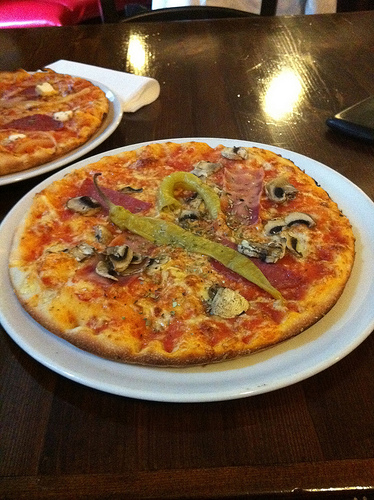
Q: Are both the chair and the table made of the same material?
A: Yes, both the chair and the table are made of wood.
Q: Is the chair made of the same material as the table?
A: Yes, both the chair and the table are made of wood.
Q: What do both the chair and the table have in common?
A: The material, both the chair and the table are wooden.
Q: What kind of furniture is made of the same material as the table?
A: The chair is made of the same material as the table.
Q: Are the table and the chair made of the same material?
A: Yes, both the table and the chair are made of wood.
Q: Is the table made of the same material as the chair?
A: Yes, both the table and the chair are made of wood.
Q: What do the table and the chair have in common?
A: The material, both the table and the chair are wooden.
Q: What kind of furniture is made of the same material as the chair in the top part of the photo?
A: The table is made of the same material as the chair.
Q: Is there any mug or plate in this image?
A: Yes, there is a plate.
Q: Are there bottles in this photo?
A: No, there are no bottles.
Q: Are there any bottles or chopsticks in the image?
A: No, there are no bottles or chopsticks.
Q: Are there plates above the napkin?
A: Yes, there is a plate above the napkin.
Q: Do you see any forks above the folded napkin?
A: No, there is a plate above the napkin.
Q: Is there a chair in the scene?
A: Yes, there is a chair.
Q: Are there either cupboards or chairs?
A: Yes, there is a chair.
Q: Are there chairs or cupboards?
A: Yes, there is a chair.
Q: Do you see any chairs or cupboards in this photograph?
A: Yes, there is a chair.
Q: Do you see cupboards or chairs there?
A: Yes, there is a chair.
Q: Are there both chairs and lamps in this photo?
A: No, there is a chair but no lamps.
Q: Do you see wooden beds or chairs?
A: Yes, there is a wood chair.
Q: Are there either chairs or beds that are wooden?
A: Yes, the chair is wooden.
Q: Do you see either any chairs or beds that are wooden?
A: Yes, the chair is wooden.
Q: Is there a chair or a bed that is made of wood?
A: Yes, the chair is made of wood.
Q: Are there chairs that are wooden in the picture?
A: Yes, there is a wood chair.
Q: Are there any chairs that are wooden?
A: Yes, there is a chair that is wooden.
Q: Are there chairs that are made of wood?
A: Yes, there is a chair that is made of wood.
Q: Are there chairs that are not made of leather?
A: Yes, there is a chair that is made of wood.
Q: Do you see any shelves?
A: No, there are no shelves.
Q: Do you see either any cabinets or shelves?
A: No, there are no shelves or cabinets.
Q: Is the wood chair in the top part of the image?
A: Yes, the chair is in the top of the image.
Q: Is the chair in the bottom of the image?
A: No, the chair is in the top of the image.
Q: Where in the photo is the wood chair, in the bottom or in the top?
A: The chair is in the top of the image.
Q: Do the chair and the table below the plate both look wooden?
A: Yes, both the chair and the table are wooden.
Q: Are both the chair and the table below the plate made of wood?
A: Yes, both the chair and the table are made of wood.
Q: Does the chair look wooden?
A: Yes, the chair is wooden.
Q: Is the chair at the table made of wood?
A: Yes, the chair is made of wood.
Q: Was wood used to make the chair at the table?
A: Yes, the chair is made of wood.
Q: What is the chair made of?
A: The chair is made of wood.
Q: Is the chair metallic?
A: No, the chair is wooden.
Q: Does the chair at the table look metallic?
A: No, the chair is wooden.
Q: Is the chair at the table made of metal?
A: No, the chair is made of wood.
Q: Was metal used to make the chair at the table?
A: No, the chair is made of wood.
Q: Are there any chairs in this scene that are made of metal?
A: No, there is a chair but it is made of wood.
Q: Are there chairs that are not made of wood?
A: No, there is a chair but it is made of wood.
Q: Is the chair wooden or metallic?
A: The chair is wooden.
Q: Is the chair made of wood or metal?
A: The chair is made of wood.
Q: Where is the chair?
A: The chair is at the table.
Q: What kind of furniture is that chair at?
A: The chair is at the table.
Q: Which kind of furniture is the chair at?
A: The chair is at the table.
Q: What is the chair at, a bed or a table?
A: The chair is at a table.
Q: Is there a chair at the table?
A: Yes, there is a chair at the table.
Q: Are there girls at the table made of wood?
A: No, there is a chair at the table.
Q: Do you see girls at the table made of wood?
A: No, there is a chair at the table.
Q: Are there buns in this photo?
A: No, there are no buns.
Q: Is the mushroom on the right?
A: Yes, the mushroom is on the right of the image.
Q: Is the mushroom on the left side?
A: No, the mushroom is on the right of the image.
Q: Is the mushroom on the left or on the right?
A: The mushroom is on the right of the image.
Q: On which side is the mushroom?
A: The mushroom is on the right of the image.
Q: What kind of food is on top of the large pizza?
A: The food is a mushroom.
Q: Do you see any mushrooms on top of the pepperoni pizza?
A: Yes, there is a mushroom on top of the pizza.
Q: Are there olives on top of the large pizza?
A: No, there is a mushroom on top of the pizza.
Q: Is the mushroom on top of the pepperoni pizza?
A: Yes, the mushroom is on top of the pizza.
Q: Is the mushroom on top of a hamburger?
A: No, the mushroom is on top of the pizza.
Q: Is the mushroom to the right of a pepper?
A: Yes, the mushroom is to the right of a pepper.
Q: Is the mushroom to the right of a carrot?
A: No, the mushroom is to the right of a pepper.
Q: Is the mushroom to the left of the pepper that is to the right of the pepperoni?
A: No, the mushroom is to the right of the pepper.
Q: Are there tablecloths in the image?
A: No, there are no tablecloths.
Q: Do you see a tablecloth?
A: No, there are no tablecloths.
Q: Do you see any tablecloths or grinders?
A: No, there are no tablecloths or grinders.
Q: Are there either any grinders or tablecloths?
A: No, there are no tablecloths or grinders.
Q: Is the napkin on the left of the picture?
A: Yes, the napkin is on the left of the image.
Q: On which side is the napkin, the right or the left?
A: The napkin is on the left of the image.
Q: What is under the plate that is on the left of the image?
A: The napkin is under the plate.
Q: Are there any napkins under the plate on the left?
A: Yes, there is a napkin under the plate.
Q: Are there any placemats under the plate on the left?
A: No, there is a napkin under the plate.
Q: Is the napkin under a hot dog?
A: No, the napkin is under the plate.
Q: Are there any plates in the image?
A: Yes, there is a plate.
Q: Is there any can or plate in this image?
A: Yes, there is a plate.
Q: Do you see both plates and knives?
A: No, there is a plate but no knives.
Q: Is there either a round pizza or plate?
A: Yes, there is a round plate.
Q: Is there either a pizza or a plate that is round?
A: Yes, the plate is round.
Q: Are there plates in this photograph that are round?
A: Yes, there is a round plate.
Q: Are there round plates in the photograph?
A: Yes, there is a round plate.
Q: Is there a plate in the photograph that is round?
A: Yes, there is a plate that is round.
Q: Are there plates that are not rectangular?
A: Yes, there is a round plate.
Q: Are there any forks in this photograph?
A: No, there are no forks.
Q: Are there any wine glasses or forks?
A: No, there are no forks or wine glasses.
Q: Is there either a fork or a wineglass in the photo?
A: No, there are no forks or wine glasses.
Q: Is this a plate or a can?
A: This is a plate.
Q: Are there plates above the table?
A: Yes, there is a plate above the table.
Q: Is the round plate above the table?
A: Yes, the plate is above the table.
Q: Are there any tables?
A: Yes, there is a table.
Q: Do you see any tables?
A: Yes, there is a table.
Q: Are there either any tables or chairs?
A: Yes, there is a table.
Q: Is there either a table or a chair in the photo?
A: Yes, there is a table.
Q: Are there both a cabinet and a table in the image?
A: No, there is a table but no cabinets.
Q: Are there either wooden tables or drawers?
A: Yes, there is a wood table.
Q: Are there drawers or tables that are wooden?
A: Yes, the table is wooden.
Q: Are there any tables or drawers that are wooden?
A: Yes, the table is wooden.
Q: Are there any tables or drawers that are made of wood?
A: Yes, the table is made of wood.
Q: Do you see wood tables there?
A: Yes, there is a wood table.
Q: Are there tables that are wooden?
A: Yes, there is a table that is wooden.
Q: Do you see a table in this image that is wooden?
A: Yes, there is a table that is wooden.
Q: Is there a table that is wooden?
A: Yes, there is a table that is wooden.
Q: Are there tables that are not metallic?
A: Yes, there is a wooden table.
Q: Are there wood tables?
A: Yes, there is a table that is made of wood.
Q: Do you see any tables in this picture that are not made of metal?
A: Yes, there is a table that is made of wood.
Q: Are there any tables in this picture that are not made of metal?
A: Yes, there is a table that is made of wood.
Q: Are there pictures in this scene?
A: No, there are no pictures.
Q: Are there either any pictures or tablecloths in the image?
A: No, there are no pictures or tablecloths.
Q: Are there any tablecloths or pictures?
A: No, there are no pictures or tablecloths.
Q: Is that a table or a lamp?
A: That is a table.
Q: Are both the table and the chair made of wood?
A: Yes, both the table and the chair are made of wood.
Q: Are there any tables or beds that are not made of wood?
A: No, there is a table but it is made of wood.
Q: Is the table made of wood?
A: Yes, the table is made of wood.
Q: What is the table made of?
A: The table is made of wood.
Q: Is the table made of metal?
A: No, the table is made of wood.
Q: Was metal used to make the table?
A: No, the table is made of wood.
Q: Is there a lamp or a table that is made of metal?
A: No, there is a table but it is made of wood.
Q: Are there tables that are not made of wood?
A: No, there is a table but it is made of wood.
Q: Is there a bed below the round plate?
A: No, there is a table below the plate.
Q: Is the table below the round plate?
A: Yes, the table is below the plate.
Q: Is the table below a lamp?
A: No, the table is below the plate.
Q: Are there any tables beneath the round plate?
A: Yes, there is a table beneath the plate.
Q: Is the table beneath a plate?
A: Yes, the table is beneath a plate.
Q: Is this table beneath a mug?
A: No, the table is beneath a plate.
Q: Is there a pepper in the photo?
A: Yes, there is a pepper.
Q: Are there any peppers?
A: Yes, there is a pepper.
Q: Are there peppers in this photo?
A: Yes, there is a pepper.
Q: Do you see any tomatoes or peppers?
A: Yes, there is a pepper.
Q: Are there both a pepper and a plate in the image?
A: Yes, there are both a pepper and a plate.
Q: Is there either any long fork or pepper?
A: Yes, there is a long pepper.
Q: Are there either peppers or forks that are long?
A: Yes, the pepper is long.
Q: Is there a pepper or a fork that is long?
A: Yes, the pepper is long.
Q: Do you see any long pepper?
A: Yes, there is a long pepper.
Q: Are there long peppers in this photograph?
A: Yes, there is a long pepper.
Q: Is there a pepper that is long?
A: Yes, there is a pepper that is long.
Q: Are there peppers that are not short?
A: Yes, there is a long pepper.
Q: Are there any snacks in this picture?
A: No, there are no snacks.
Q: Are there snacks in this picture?
A: No, there are no snacks.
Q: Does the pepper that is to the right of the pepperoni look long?
A: Yes, the pepper is long.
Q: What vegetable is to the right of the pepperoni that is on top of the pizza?
A: The vegetable is a pepper.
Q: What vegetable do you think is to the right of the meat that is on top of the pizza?
A: The vegetable is a pepper.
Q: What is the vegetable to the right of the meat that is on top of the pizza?
A: The vegetable is a pepper.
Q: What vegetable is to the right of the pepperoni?
A: The vegetable is a pepper.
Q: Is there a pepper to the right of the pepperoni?
A: Yes, there is a pepper to the right of the pepperoni.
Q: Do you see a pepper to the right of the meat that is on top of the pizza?
A: Yes, there is a pepper to the right of the pepperoni.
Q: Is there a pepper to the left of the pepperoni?
A: No, the pepper is to the right of the pepperoni.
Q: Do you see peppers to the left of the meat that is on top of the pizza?
A: No, the pepper is to the right of the pepperoni.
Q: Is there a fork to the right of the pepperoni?
A: No, there is a pepper to the right of the pepperoni.